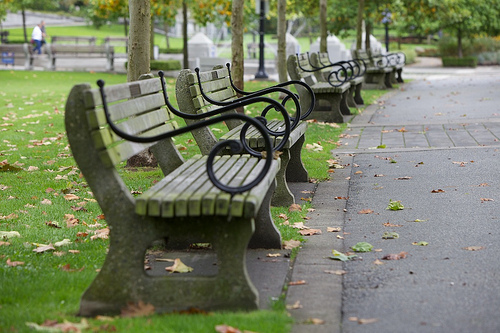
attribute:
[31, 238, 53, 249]
leaf — brown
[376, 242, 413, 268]
leaf — brown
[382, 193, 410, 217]
leaf — green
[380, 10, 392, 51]
lampost — black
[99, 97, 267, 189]
ornamental — iron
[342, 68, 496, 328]
walkway — cement